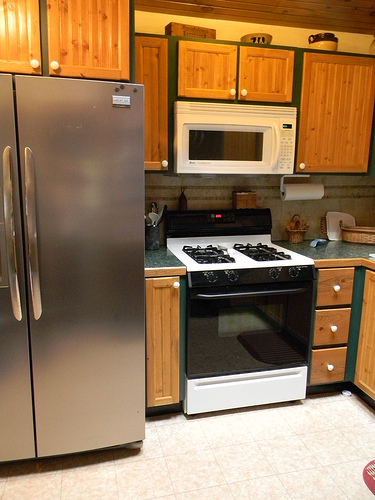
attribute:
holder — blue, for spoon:
[308, 237, 326, 247]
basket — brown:
[345, 212, 373, 251]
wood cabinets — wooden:
[157, 37, 295, 102]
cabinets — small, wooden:
[166, 40, 296, 102]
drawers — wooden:
[147, 203, 373, 401]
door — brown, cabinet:
[238, 47, 294, 103]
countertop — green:
[287, 239, 374, 264]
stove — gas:
[160, 208, 314, 418]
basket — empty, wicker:
[336, 215, 374, 247]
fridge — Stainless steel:
[0, 71, 146, 462]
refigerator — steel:
[0, 72, 146, 460]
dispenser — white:
[278, 172, 311, 194]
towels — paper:
[281, 183, 326, 200]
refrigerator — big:
[4, 65, 152, 455]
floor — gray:
[0, 386, 372, 499]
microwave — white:
[173, 100, 299, 175]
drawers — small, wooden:
[289, 254, 349, 383]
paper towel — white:
[273, 173, 338, 206]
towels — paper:
[279, 182, 331, 201]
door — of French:
[16, 70, 150, 456]